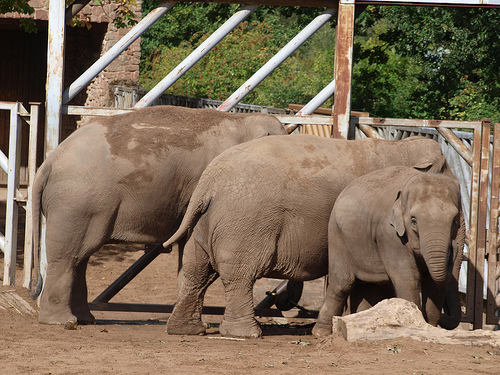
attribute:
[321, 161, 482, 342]
elephant — small, baby, infant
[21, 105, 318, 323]
elephant — large, adult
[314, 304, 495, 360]
log — large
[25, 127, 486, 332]
elephants — together, family, different sized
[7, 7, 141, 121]
wall — stone, brick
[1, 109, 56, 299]
fence — metal, wooden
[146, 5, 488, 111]
trees — green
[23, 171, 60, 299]
tail — long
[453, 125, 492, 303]
gate — wooden, rusty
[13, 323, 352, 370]
ground — dirty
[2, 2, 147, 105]
building — brick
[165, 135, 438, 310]
elephant — in middle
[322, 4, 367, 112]
fence — rusty